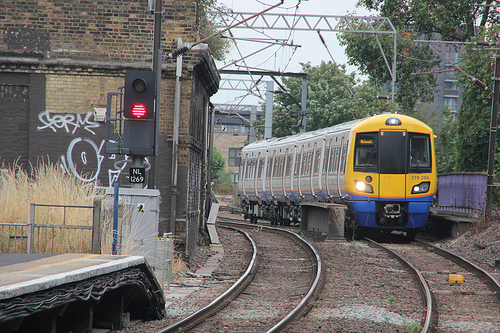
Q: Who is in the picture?
A: Nobody.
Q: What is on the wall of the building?
A: Graffiti.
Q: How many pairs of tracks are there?
A: Two.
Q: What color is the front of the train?
A: Yellow.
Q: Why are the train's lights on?
A: Safety.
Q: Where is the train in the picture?
A: On the right track.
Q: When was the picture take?
A: Daytime.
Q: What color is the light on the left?
A: Red.